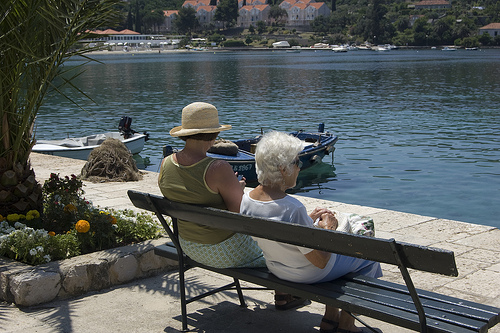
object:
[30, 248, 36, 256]
flower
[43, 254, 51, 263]
flower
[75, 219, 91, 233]
flower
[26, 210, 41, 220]
flower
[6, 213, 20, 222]
flower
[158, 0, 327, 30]
buildings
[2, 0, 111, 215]
palm tree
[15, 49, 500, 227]
lake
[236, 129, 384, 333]
ladies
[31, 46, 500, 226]
water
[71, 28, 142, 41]
resort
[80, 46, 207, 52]
beach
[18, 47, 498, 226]
bay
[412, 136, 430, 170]
ground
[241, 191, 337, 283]
shirt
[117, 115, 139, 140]
motor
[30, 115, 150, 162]
boat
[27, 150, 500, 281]
seawall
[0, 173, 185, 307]
bed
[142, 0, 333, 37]
development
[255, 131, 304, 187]
hair.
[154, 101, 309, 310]
lady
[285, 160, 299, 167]
glasses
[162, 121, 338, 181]
boat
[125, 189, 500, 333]
bench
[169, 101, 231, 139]
hat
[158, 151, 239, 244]
tank top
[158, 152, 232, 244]
shirt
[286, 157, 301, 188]
face